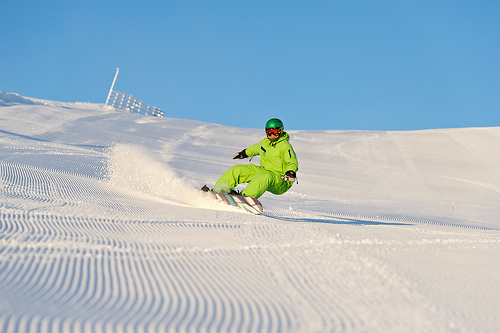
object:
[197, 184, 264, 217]
snowboard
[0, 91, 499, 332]
ground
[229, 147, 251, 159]
glove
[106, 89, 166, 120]
fence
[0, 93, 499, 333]
snow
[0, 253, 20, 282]
treads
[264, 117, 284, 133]
helmet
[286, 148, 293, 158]
zipper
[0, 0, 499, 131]
sky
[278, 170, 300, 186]
glove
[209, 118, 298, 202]
man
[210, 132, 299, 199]
snow suit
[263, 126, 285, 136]
goggles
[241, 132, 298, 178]
jacket